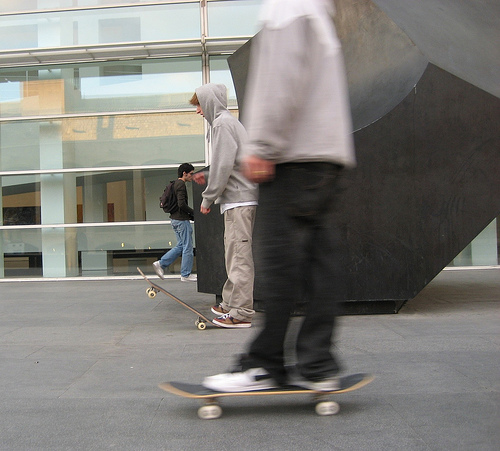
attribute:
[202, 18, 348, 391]
person — skateboarding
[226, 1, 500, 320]
sculpture — black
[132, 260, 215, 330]
skateboard — black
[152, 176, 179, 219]
backpack — black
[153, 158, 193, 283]
man — walking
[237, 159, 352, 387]
pants — black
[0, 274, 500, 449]
sidewalk — gray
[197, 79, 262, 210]
sweatshirt — gray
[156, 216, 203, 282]
pants — blue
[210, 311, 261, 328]
foot — brown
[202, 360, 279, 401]
sneaker — white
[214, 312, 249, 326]
shoe — brown